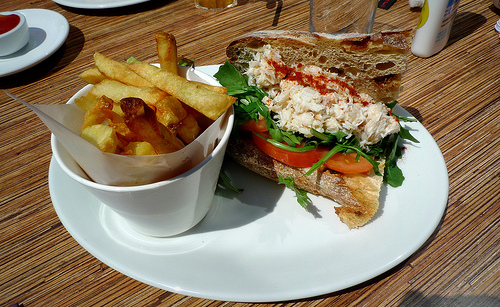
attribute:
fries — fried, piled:
[75, 32, 237, 155]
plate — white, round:
[49, 63, 448, 302]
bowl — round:
[0, 13, 28, 56]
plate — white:
[0, 9, 69, 75]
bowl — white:
[50, 64, 234, 237]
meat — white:
[243, 45, 399, 151]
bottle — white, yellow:
[411, 0, 458, 58]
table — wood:
[0, 0, 499, 305]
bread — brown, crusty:
[227, 28, 415, 102]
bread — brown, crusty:
[227, 135, 385, 229]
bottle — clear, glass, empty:
[309, 0, 379, 34]